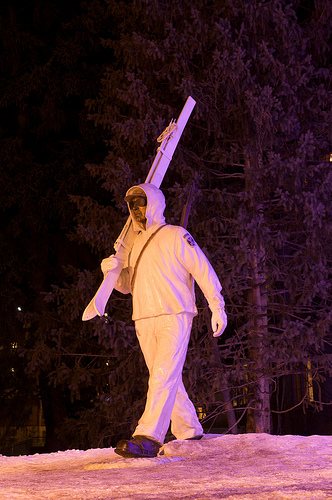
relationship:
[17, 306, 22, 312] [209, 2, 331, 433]
lights through trees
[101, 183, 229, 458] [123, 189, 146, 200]
man has a baseball cap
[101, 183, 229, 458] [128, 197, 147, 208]
man wearing sunglasses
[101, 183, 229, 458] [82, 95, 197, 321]
man walking with skis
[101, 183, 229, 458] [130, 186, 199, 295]
skier has a rifle strap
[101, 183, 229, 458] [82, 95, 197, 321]
man carrying skis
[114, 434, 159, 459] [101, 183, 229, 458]
cross country boots on skier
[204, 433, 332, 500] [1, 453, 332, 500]
slushy snow on ground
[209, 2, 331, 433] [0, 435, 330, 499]
trees line trail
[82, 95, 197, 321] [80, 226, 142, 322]
skis are on mans shoulder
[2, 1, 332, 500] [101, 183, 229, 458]
picture of a skier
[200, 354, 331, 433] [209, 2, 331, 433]
house behind trees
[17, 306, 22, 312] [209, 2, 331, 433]
lights behind trees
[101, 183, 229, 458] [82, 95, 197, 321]
man with skis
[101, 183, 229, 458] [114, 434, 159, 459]
skier has on ski boots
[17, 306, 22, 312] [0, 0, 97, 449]
lights behind trees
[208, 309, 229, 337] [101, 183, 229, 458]
gloves on skier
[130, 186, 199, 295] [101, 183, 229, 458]
rifle strap on skier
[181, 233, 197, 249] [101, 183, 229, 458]
arm patch on ski suit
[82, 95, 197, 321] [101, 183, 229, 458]
skis are carried by skier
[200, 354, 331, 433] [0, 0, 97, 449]
building behind trees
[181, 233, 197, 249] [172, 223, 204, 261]
patch on shoulder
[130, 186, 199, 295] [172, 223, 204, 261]
rifle strap over shoulder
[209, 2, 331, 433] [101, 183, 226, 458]
trees behind man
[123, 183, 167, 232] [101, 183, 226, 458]
hood over man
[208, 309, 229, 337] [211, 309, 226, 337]
gloves on hand